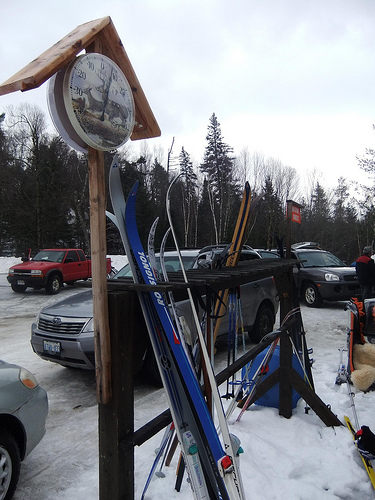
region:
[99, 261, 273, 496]
this is a ski lodge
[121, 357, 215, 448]
these are some skis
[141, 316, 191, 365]
the ski is blue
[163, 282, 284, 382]
these are ski poles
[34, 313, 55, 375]
this is a plate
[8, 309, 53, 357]
the plate is white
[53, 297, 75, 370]
this is a logo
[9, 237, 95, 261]
this is a window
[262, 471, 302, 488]
this is a lot of snow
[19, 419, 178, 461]
this is a fence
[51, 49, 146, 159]
white clock with animals on it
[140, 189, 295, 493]
skis leaning in a ski rack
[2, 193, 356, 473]
cars parked on the street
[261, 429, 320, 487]
ground covered with white snow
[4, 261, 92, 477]
street covered with white snow and ice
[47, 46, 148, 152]
white clock with black hands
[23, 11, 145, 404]
wooden clock post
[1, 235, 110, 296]
red truck with one door open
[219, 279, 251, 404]
ski poles hanging on the ski rack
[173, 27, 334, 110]
white clouds covering the light blue skky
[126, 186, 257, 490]
these are some skis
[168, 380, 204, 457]
the skis are long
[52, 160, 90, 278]
this is a pole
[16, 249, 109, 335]
the pole is wooden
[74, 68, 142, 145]
this is a clock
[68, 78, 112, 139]
the clock is round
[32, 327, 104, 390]
this is a plate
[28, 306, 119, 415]
the plate is for white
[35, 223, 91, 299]
this is some windows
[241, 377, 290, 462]
the ground has lots of snow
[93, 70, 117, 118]
hand on the thermometer.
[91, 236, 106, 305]
post supporting the thermometer.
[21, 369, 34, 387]
headlight on the car.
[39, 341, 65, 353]
license plate on the car.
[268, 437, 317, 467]
snow on the ground.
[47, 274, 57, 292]
tire on the truck.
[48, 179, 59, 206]
leaves on the tree.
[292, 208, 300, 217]
red sign on posts.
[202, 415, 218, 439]
blue paint on ski.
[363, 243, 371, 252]
cap on man's head.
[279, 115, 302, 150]
part of a cloud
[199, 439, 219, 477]
part of a metal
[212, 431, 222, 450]
part of a line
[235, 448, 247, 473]
part of a wheel